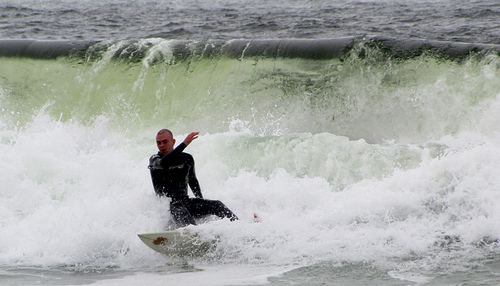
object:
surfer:
[147, 128, 240, 228]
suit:
[148, 142, 243, 227]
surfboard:
[135, 231, 217, 256]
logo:
[152, 236, 168, 245]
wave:
[1, 39, 500, 265]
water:
[1, 1, 499, 45]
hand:
[182, 132, 200, 147]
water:
[0, 255, 499, 286]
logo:
[169, 164, 184, 169]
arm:
[147, 130, 200, 168]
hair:
[157, 128, 174, 140]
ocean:
[1, 2, 498, 283]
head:
[156, 128, 176, 156]